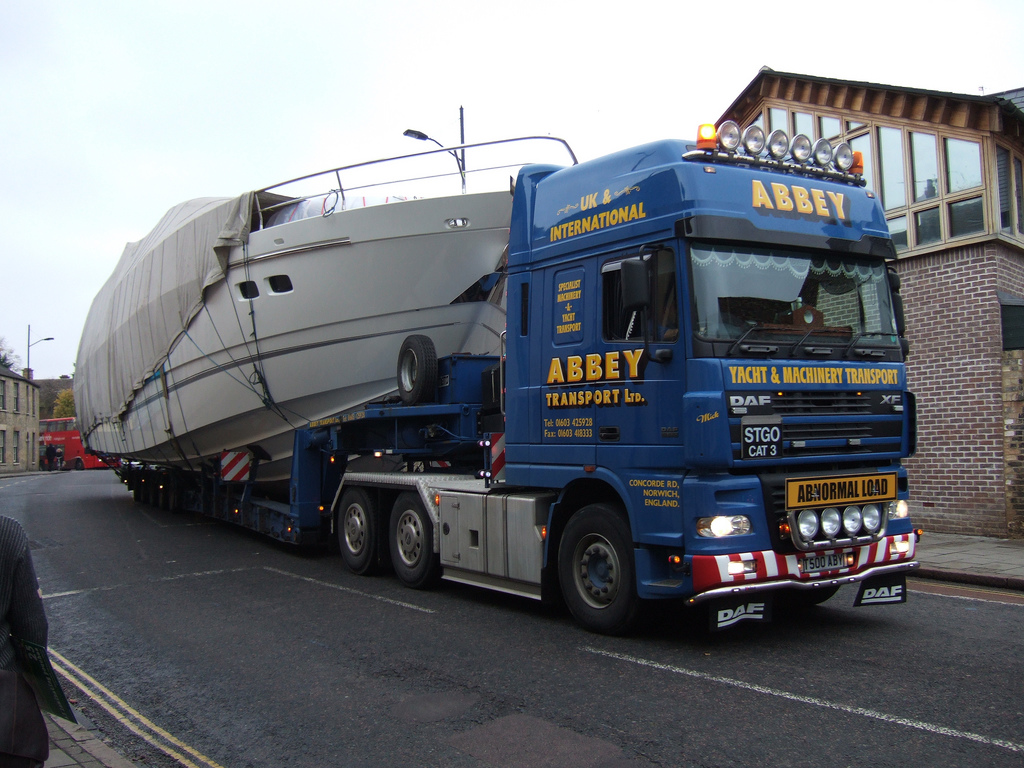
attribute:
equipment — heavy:
[61, 128, 583, 473]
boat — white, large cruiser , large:
[65, 128, 585, 473]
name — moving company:
[739, 169, 852, 225]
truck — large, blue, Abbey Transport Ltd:
[67, 122, 931, 642]